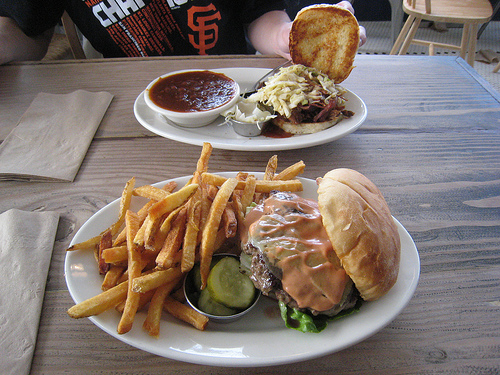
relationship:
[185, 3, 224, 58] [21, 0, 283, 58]
logo on shirt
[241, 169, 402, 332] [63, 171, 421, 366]
hamburger on plate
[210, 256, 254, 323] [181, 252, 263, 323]
pickles in cup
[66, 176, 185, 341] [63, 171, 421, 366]
fries on plate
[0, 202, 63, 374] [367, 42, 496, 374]
napkin on table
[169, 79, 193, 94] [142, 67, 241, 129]
beans in bowl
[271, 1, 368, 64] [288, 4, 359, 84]
hand holding bun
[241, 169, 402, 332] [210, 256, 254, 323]
burger fries pickles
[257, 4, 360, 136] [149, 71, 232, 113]
sandwich slaw chili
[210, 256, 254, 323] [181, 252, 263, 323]
pickle on side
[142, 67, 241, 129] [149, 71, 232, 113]
bowl of chili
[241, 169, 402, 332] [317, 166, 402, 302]
burger has bun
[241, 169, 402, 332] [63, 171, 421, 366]
burger on plate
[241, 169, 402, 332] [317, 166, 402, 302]
hamburger bun top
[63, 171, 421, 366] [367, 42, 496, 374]
plate on table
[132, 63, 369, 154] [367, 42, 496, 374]
plate on table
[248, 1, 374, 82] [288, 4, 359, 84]
person holding bun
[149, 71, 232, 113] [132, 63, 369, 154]
chili on plate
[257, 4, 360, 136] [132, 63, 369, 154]
sandwich on plate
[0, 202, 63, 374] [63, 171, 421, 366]
napkin near plate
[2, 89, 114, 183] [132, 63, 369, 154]
napkin near plate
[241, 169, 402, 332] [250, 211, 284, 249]
burger has cheese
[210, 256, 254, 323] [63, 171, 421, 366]
pickles on plate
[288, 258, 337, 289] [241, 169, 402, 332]
dressing on hamburger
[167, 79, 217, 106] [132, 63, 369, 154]
chili in plate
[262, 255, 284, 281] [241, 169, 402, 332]
onions on hamburger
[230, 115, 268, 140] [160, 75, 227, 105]
cup of sauce